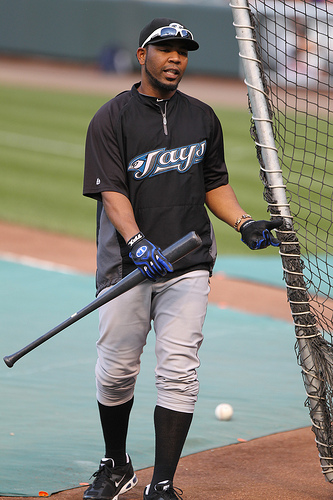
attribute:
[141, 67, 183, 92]
beard — black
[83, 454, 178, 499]
shoes — black, white, Nike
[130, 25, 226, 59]
sunglasses — white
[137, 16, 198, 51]
hat — black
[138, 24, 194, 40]
glasses — silver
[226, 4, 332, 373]
pole — metal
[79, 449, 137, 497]
cleats — white, black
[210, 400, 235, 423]
baseball — white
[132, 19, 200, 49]
hat — black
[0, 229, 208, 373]
baseball bat — black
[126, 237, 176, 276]
glove — blue, black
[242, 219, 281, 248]
glove — blue, black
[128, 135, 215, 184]
logo — JAYS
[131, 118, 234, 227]
jersey — black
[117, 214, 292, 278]
gloves — black, blue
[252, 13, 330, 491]
net — large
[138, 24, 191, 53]
sunglasses — white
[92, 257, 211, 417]
pants — gray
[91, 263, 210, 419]
shorts — grey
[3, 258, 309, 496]
tarp — green